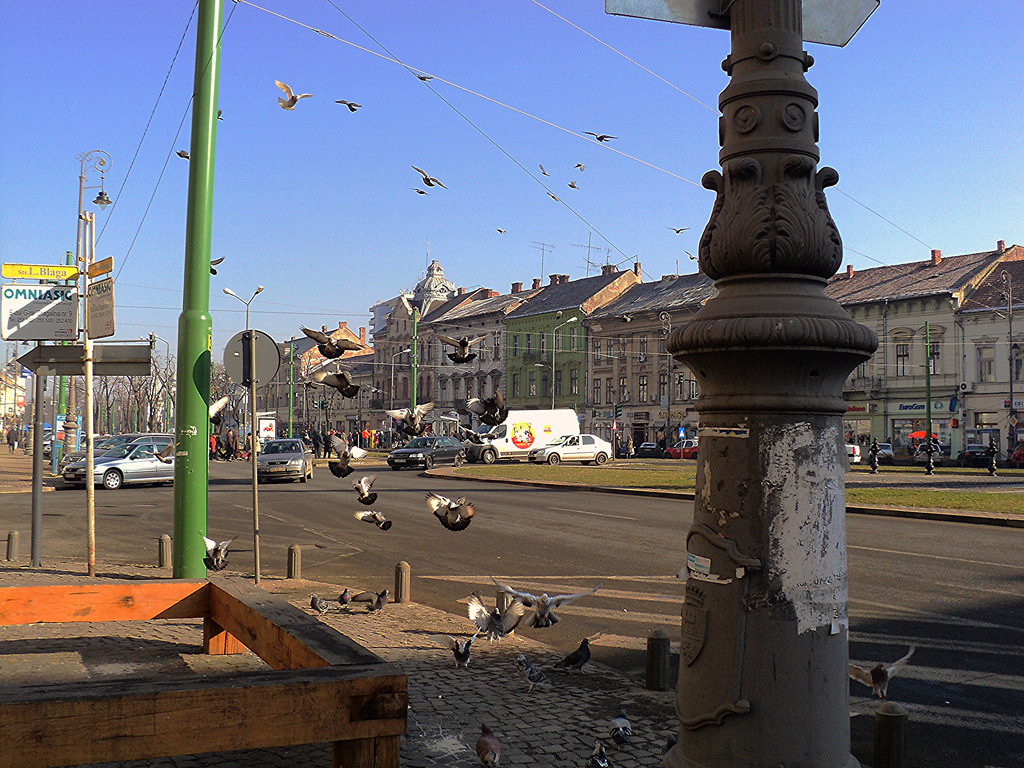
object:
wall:
[948, 389, 1024, 463]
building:
[0, 242, 1024, 466]